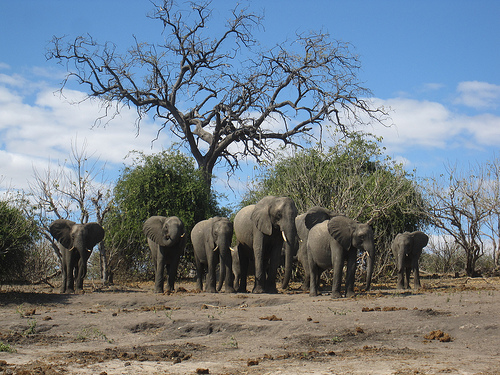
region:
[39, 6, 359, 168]
Large dead tree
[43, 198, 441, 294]
Herd of elephants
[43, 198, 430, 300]
Six elephants that can actually be seen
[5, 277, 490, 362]
Large area of ground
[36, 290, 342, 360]
Holes and little hills in dirt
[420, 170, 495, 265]
Small dead tree on right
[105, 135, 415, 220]
Green trees in background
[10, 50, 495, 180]
Big blue sky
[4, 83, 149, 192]
White clouds in the blue sky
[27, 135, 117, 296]
Dead tree on the left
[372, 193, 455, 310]
an elephant standing in a field.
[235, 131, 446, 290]
a tree filled with leaves.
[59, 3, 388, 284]
a tree in a field of dry grass.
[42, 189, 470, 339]
a herd of elephants on a dirt field.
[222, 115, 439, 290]
a tree with lots of green leaves.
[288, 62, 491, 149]
a cloud in a blue sky.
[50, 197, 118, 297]
an elephant standing in a dirt field.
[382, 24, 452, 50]
a section of clear blue sky.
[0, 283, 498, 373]
a field with patches of grass.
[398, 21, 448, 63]
a section of clear blue sky.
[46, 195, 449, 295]
group of gray elephants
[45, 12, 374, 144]
leafless tree behind elephants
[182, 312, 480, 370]
dirt and sand on the ground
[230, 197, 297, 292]
tall elephant standing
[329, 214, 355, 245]
ear of gray elephant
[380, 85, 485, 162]
white clouds in the sky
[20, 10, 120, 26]
clear sunny blue sky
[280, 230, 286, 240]
white tusk of elephant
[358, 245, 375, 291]
nose of gray elephant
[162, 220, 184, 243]
head of gray elephant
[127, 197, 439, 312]
herd of grey elephants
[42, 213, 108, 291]
elephant with ears fanned out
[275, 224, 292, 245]
white tusk of elephant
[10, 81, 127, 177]
large white fluffy clouds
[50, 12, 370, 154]
tree with no leaves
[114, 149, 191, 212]
tree with green leaves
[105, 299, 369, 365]
dusty dirt ground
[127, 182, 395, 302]
elephants standing on dirt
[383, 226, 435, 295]
small grey elephant by tree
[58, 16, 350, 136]
tall bare tree behind elephants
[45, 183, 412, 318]
pack of elephants are walking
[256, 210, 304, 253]
elephant has white tusks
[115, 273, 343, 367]
bare ground under elephants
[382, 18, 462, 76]
sky is blue and cloudy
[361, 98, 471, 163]
white puffy clouds in sky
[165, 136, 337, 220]
green trees behind bare tree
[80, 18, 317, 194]
tree behind elephants is tall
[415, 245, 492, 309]
brown grass on ground behind rightmost elephant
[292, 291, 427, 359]
dirt clumps on bare ground